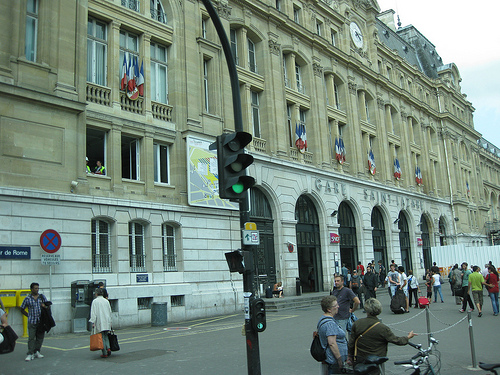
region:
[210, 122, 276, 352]
traffic light on pole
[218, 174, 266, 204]
glowing green traffic light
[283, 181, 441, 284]
arches over building doorways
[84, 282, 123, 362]
woman carrying two bags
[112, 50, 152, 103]
flags in front of window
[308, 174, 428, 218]
words on building front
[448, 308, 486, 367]
metal poles with chains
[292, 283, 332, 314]
stairs in front of doorway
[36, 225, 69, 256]
round blue and red sign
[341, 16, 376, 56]
clock on front of building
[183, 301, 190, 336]
bottom of a building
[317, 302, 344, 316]
head of a woman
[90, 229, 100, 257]
edge of a wall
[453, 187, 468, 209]
part of a building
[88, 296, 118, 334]
Woman dressed in white jacket.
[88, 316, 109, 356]
Woman carrying a brown purse.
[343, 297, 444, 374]
Person standing next to bicycle.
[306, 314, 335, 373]
Woman carrying black purse over shoulder.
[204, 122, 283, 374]
Traffic light on corner of street.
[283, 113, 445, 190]
Flags mounted outside windows along side of building.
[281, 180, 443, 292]
Doors along side of building.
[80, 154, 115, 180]
Two people in front of window on building.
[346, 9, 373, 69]
Clock on front of building.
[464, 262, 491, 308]
Person dressed in green shirt and gray pants.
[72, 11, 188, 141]
Flags in a window balcony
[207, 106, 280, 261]
Green light lit on street light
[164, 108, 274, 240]
Map hung on building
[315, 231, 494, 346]
people milling on sidewalk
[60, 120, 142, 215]
construction workers in window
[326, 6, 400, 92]
large clock on building face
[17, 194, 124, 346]
Blue and red street sign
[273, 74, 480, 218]
Multiple flags in windows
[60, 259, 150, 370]
woman with bags in each hand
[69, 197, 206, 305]
windows with metal bars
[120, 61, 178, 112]
plenty flags are visible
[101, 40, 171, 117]
plenty flags are visible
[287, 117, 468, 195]
plenty flags are visible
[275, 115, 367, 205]
plenty flags are visible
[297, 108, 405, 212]
plenty flags are visible